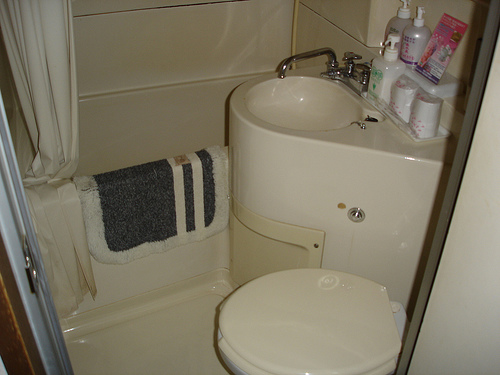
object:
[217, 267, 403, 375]
toilet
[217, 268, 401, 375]
lid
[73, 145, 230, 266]
rug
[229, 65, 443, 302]
sink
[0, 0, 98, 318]
curtain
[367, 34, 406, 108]
dispenser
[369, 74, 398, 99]
soap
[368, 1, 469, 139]
supplies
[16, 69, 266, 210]
bathtub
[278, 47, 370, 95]
faucet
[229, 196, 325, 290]
storage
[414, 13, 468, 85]
paper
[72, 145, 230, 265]
mat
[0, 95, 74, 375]
door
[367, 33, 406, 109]
bottle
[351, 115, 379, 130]
stopper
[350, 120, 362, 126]
chain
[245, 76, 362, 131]
tub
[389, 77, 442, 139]
cups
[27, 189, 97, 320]
towel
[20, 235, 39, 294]
hinge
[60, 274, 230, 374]
baseboard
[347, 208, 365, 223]
button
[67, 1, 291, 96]
wall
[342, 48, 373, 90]
handles